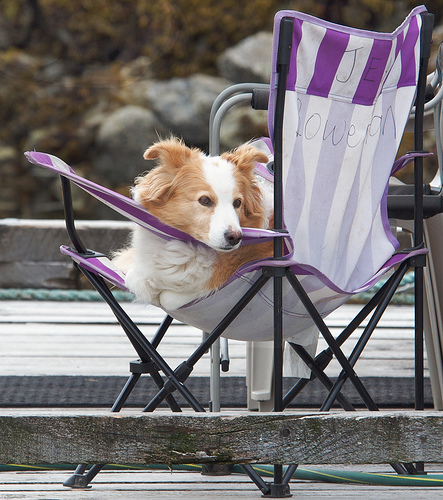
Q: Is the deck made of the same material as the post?
A: Yes, both the deck and the post are made of wood.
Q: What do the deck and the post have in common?
A: The material, both the deck and the post are wooden.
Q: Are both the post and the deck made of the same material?
A: Yes, both the post and the deck are made of wood.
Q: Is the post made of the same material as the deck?
A: Yes, both the post and the deck are made of wood.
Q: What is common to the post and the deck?
A: The material, both the post and the deck are wooden.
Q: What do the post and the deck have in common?
A: The material, both the post and the deck are wooden.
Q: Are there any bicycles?
A: No, there are no bicycles.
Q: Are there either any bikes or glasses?
A: No, there are no bikes or glasses.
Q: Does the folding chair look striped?
A: Yes, the folding chair is striped.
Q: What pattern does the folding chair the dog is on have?
A: The folding chair has striped pattern.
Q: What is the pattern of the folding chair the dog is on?
A: The folding chair is striped.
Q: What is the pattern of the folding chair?
A: The folding chair is striped.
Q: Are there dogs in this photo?
A: Yes, there is a dog.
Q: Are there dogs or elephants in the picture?
A: Yes, there is a dog.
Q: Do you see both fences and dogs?
A: No, there is a dog but no fences.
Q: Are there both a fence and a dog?
A: No, there is a dog but no fences.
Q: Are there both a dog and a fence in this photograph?
A: No, there is a dog but no fences.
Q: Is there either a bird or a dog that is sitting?
A: Yes, the dog is sitting.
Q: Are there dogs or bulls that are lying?
A: Yes, the dog is lying.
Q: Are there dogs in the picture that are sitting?
A: Yes, there is a dog that is sitting.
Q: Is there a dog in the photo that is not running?
A: Yes, there is a dog that is sitting.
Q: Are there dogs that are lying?
A: Yes, there is a dog that is lying.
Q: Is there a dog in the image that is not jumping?
A: Yes, there is a dog that is lying.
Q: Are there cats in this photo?
A: No, there are no cats.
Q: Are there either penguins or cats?
A: No, there are no cats or penguins.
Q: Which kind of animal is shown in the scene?
A: The animal is a dog.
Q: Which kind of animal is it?
A: The animal is a dog.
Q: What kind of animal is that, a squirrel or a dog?
A: This is a dog.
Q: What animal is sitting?
A: The animal is a dog.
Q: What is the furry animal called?
A: The animal is a dog.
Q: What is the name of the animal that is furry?
A: The animal is a dog.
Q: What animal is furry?
A: The animal is a dog.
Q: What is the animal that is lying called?
A: The animal is a dog.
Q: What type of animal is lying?
A: The animal is a dog.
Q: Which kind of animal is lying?
A: The animal is a dog.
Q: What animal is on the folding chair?
A: The dog is on the folding chair.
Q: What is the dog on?
A: The dog is on the folding chair.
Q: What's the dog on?
A: The dog is on the folding chair.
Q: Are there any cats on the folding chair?
A: No, there is a dog on the folding chair.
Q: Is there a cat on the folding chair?
A: No, there is a dog on the folding chair.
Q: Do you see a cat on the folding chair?
A: No, there is a dog on the folding chair.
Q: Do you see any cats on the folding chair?
A: No, there is a dog on the folding chair.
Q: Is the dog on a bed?
A: No, the dog is on a folding chair.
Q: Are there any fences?
A: No, there are no fences.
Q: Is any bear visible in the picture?
A: No, there are no bears.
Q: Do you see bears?
A: No, there are no bears.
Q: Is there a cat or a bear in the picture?
A: No, there are no bears or cats.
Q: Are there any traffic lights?
A: No, there are no traffic lights.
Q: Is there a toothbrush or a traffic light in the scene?
A: No, there are no traffic lights or toothbrushes.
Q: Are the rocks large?
A: Yes, the rocks are large.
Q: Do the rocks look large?
A: Yes, the rocks are large.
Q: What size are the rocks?
A: The rocks are large.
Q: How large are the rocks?
A: The rocks are large.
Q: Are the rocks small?
A: No, the rocks are large.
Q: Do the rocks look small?
A: No, the rocks are large.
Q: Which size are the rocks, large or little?
A: The rocks are large.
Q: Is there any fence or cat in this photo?
A: No, there are no fences or cats.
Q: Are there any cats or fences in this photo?
A: No, there are no fences or cats.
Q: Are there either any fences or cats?
A: No, there are no fences or cats.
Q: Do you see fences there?
A: No, there are no fences.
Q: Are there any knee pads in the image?
A: No, there are no knee pads.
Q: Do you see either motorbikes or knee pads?
A: No, there are no knee pads or motorbikes.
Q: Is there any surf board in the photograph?
A: No, there are no surfboards.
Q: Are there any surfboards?
A: No, there are no surfboards.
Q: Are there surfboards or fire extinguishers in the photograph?
A: No, there are no surfboards or fire extinguishers.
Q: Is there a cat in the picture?
A: No, there are no cats.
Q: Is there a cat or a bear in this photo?
A: No, there are no cats or bears.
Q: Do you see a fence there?
A: No, there are no fences.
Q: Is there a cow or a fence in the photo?
A: No, there are no fences or cows.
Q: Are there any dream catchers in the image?
A: No, there are no dream catchers.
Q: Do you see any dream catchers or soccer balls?
A: No, there are no dream catchers or soccer balls.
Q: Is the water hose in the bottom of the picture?
A: Yes, the water hose is in the bottom of the image.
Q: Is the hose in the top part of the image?
A: No, the hose is in the bottom of the image.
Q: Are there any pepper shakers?
A: No, there are no pepper shakers.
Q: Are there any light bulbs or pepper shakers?
A: No, there are no pepper shakers or light bulbs.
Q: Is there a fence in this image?
A: No, there are no fences.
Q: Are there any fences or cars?
A: No, there are no fences or cars.